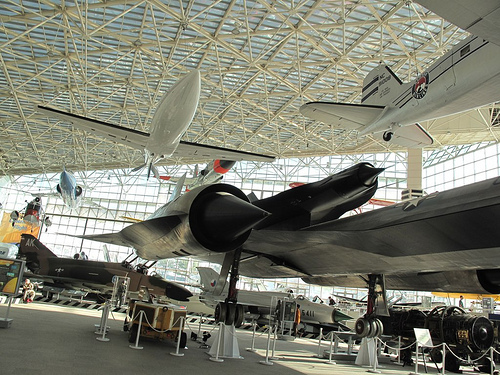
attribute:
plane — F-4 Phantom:
[15, 233, 193, 303]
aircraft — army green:
[29, 72, 276, 187]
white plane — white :
[34, 68, 281, 180]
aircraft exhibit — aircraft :
[4, 6, 499, 373]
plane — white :
[35, 69, 275, 174]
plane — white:
[298, 0, 498, 146]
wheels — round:
[213, 300, 243, 327]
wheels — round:
[353, 316, 382, 340]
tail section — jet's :
[16, 232, 59, 275]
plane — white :
[9, 73, 294, 183]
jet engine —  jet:
[126, 177, 276, 287]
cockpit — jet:
[114, 255, 161, 284]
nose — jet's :
[157, 63, 212, 125]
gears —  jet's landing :
[211, 292, 252, 325]